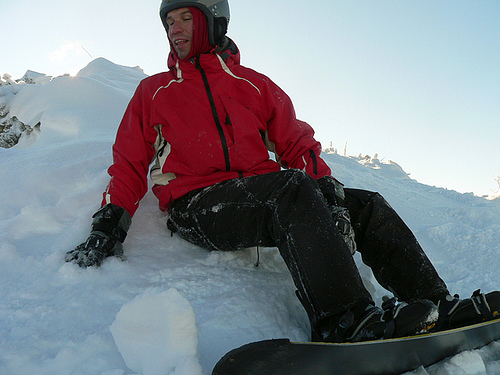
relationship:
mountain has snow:
[43, 60, 115, 136] [59, 122, 104, 155]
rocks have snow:
[9, 112, 46, 155] [59, 122, 104, 155]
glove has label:
[82, 203, 134, 275] [101, 188, 113, 203]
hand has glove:
[63, 200, 131, 277] [82, 203, 134, 275]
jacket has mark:
[116, 53, 316, 178] [218, 100, 253, 166]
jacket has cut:
[116, 53, 316, 178] [142, 130, 181, 199]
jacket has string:
[116, 53, 316, 178] [254, 240, 266, 270]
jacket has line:
[116, 53, 316, 178] [209, 54, 264, 101]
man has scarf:
[104, 2, 429, 327] [187, 11, 218, 55]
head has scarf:
[157, 4, 232, 63] [187, 11, 218, 55]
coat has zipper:
[116, 53, 316, 178] [190, 62, 233, 167]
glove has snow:
[82, 203, 134, 275] [59, 122, 104, 155]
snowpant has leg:
[204, 171, 427, 306] [236, 173, 348, 312]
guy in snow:
[104, 2, 429, 327] [59, 122, 104, 155]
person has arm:
[104, 2, 429, 327] [99, 103, 160, 248]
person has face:
[104, 2, 429, 327] [165, 12, 200, 52]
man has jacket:
[104, 2, 429, 327] [116, 53, 316, 178]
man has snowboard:
[104, 2, 429, 327] [221, 330, 476, 369]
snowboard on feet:
[221, 330, 476, 369] [323, 277, 497, 328]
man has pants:
[104, 2, 429, 327] [204, 171, 427, 306]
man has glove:
[104, 2, 429, 327] [82, 203, 134, 275]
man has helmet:
[104, 2, 429, 327] [161, 2, 233, 46]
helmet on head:
[161, 2, 233, 46] [157, 4, 232, 63]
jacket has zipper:
[116, 53, 316, 178] [190, 62, 233, 167]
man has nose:
[104, 2, 429, 327] [167, 20, 186, 34]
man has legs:
[104, 2, 429, 327] [244, 174, 448, 295]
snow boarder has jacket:
[104, 2, 429, 327] [116, 53, 316, 178]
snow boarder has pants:
[104, 2, 429, 327] [204, 171, 427, 306]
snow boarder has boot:
[104, 2, 429, 327] [362, 299, 440, 335]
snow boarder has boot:
[104, 2, 429, 327] [454, 289, 496, 317]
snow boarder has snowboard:
[104, 2, 429, 327] [221, 330, 476, 369]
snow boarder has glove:
[104, 2, 429, 327] [82, 203, 134, 275]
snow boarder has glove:
[104, 2, 429, 327] [320, 173, 361, 250]